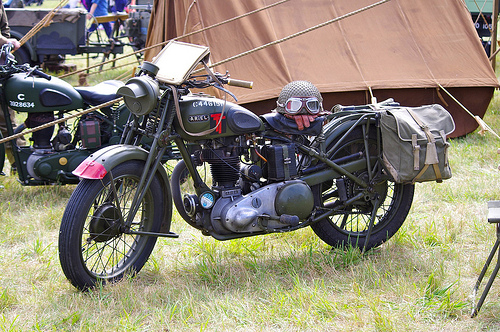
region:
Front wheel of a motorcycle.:
[57, 152, 172, 286]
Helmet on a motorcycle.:
[278, 78, 324, 118]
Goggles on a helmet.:
[277, 94, 323, 115]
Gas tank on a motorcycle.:
[175, 95, 269, 138]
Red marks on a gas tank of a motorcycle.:
[207, 110, 227, 136]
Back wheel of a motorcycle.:
[298, 111, 418, 253]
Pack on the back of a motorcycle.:
[378, 103, 455, 188]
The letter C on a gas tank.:
[16, 90, 28, 98]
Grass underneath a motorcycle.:
[202, 241, 287, 275]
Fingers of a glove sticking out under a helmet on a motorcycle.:
[282, 110, 320, 128]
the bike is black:
[61, 39, 498, 326]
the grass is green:
[237, 260, 351, 330]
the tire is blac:
[61, 159, 171, 326]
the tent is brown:
[288, 25, 446, 102]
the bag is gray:
[379, 97, 471, 206]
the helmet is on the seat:
[265, 69, 372, 171]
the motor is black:
[163, 105, 375, 257]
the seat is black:
[73, 79, 135, 109]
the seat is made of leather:
[52, 68, 157, 143]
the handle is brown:
[215, 72, 265, 94]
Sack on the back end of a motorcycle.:
[373, 105, 460, 186]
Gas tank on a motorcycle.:
[4, 70, 81, 110]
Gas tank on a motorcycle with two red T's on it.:
[172, 95, 269, 138]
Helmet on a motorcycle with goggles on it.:
[278, 81, 323, 113]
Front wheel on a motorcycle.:
[54, 155, 166, 290]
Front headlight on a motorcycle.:
[114, 76, 159, 115]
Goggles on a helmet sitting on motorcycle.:
[273, 97, 323, 115]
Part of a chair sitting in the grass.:
[467, 192, 498, 317]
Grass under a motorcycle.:
[188, 240, 219, 256]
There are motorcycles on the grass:
[10, 17, 483, 324]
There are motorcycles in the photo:
[5, 41, 470, 325]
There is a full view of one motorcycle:
[33, 21, 448, 308]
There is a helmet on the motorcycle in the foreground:
[12, 30, 454, 312]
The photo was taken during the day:
[28, 17, 473, 315]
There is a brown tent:
[140, 11, 496, 173]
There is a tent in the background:
[130, 9, 497, 138]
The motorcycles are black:
[0, 26, 491, 304]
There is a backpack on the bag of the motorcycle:
[258, 37, 493, 289]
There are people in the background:
[42, 1, 231, 100]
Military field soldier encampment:
[19, 5, 492, 161]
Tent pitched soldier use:
[140, 1, 336, 82]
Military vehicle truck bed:
[9, 2, 96, 64]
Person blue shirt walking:
[79, 0, 128, 52]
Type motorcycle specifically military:
[118, 39, 460, 254]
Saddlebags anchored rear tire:
[365, 94, 471, 184]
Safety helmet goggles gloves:
[269, 76, 338, 133]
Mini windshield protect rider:
[138, 39, 223, 86]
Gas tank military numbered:
[173, 91, 273, 141]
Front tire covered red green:
[57, 121, 188, 298]